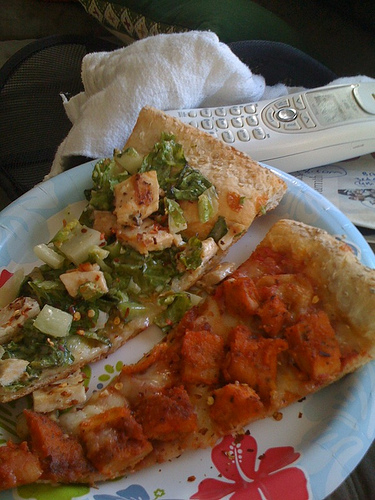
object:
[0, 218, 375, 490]
pizza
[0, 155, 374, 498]
plate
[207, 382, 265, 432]
meat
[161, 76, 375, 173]
phone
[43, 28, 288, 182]
cloth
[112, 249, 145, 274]
vegetable